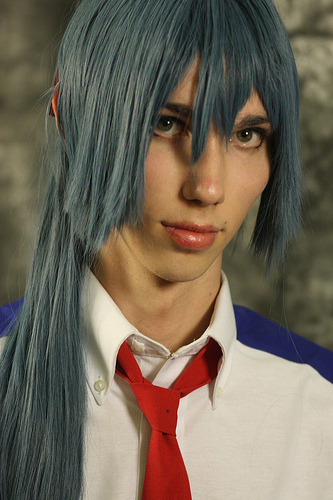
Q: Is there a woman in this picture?
A: No, there are no women.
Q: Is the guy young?
A: Yes, the guy is young.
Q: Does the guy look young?
A: Yes, the guy is young.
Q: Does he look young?
A: Yes, the guy is young.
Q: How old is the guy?
A: The guy is young.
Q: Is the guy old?
A: No, the guy is young.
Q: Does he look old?
A: No, the guy is young.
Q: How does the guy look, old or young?
A: The guy is young.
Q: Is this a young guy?
A: Yes, this is a young guy.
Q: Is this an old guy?
A: No, this is a young guy.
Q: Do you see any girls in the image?
A: No, there are no girls.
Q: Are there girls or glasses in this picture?
A: No, there are no girls or glasses.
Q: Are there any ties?
A: Yes, there is a tie.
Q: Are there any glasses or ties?
A: Yes, there is a tie.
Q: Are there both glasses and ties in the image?
A: No, there is a tie but no glasses.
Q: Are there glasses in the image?
A: No, there are no glasses.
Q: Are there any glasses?
A: No, there are no glasses.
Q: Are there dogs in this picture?
A: No, there are no dogs.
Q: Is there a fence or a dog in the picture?
A: No, there are no dogs or fences.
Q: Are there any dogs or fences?
A: No, there are no dogs or fences.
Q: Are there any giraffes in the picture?
A: No, there are no giraffes.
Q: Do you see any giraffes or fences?
A: No, there are no giraffes or fences.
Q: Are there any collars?
A: Yes, there is a collar.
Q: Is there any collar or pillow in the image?
A: Yes, there is a collar.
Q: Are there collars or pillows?
A: Yes, there is a collar.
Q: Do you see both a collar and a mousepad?
A: No, there is a collar but no mouse pads.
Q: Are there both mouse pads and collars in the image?
A: No, there is a collar but no mouse pads.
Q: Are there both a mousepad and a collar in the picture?
A: No, there is a collar but no mouse pads.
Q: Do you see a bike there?
A: No, there are no bikes.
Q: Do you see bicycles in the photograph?
A: No, there are no bicycles.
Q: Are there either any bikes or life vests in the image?
A: No, there are no bikes or life vests.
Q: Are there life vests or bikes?
A: No, there are no bikes or life vests.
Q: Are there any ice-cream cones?
A: No, there are no ice-cream cones.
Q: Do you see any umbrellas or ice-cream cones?
A: No, there are no ice-cream cones or umbrellas.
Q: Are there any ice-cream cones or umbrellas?
A: No, there are no ice-cream cones or umbrellas.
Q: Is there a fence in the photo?
A: No, there are no fences.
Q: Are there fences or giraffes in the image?
A: No, there are no fences or giraffes.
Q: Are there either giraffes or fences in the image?
A: No, there are no fences or giraffes.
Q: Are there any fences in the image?
A: No, there are no fences.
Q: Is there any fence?
A: No, there are no fences.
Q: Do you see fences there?
A: No, there are no fences.